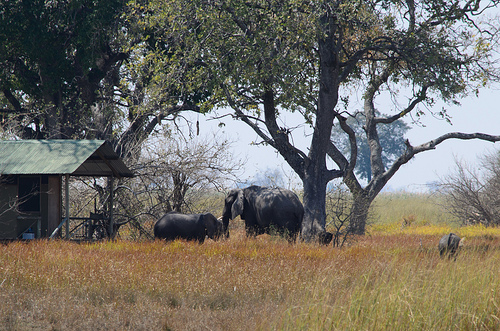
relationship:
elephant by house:
[223, 179, 300, 233] [5, 142, 123, 242]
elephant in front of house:
[141, 210, 215, 241] [5, 142, 123, 242]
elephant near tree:
[223, 179, 300, 233] [255, 30, 355, 184]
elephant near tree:
[223, 179, 300, 233] [348, 52, 414, 238]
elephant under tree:
[223, 179, 300, 233] [255, 30, 355, 184]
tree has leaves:
[255, 30, 355, 184] [295, 65, 310, 82]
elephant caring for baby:
[223, 179, 300, 233] [141, 210, 215, 241]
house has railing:
[5, 142, 123, 242] [57, 214, 86, 223]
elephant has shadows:
[223, 179, 300, 233] [270, 195, 298, 221]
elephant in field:
[223, 179, 300, 233] [46, 242, 426, 318]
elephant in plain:
[223, 179, 300, 233] [376, 225, 435, 277]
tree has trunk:
[255, 30, 355, 184] [309, 152, 324, 223]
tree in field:
[329, 182, 342, 191] [46, 242, 426, 318]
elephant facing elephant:
[223, 179, 300, 233] [141, 210, 215, 241]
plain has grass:
[376, 225, 435, 277] [209, 257, 263, 297]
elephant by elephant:
[223, 179, 300, 233] [141, 210, 215, 241]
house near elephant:
[5, 142, 123, 242] [141, 210, 215, 241]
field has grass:
[46, 242, 426, 318] [209, 257, 263, 297]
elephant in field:
[141, 210, 215, 241] [46, 242, 426, 318]